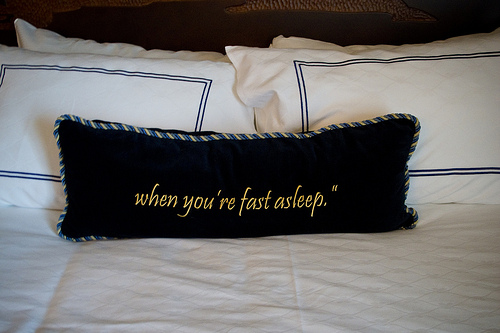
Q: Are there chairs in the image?
A: No, there are no chairs.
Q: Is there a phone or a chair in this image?
A: No, there are no chairs or phones.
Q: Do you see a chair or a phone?
A: No, there are no chairs or phones.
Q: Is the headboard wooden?
A: Yes, the headboard is wooden.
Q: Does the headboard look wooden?
A: Yes, the headboard is wooden.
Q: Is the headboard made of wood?
A: Yes, the headboard is made of wood.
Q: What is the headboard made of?
A: The headboard is made of wood.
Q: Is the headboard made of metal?
A: No, the headboard is made of wood.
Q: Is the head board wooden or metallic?
A: The head board is wooden.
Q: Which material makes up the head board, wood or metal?
A: The head board is made of wood.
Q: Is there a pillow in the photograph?
A: Yes, there are pillows.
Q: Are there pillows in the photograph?
A: Yes, there are pillows.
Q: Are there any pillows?
A: Yes, there are pillows.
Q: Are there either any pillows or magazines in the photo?
A: Yes, there are pillows.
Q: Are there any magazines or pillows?
A: Yes, there are pillows.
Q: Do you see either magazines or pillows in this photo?
A: Yes, there are pillows.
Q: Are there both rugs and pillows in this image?
A: No, there are pillows but no rugs.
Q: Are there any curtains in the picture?
A: No, there are no curtains.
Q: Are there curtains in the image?
A: No, there are no curtains.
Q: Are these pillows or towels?
A: These are pillows.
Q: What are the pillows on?
A: The pillows are on the bed.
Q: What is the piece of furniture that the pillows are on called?
A: The piece of furniture is a bed.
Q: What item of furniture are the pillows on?
A: The pillows are on the bed.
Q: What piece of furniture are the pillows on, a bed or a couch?
A: The pillows are on a bed.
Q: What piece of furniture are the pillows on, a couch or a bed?
A: The pillows are on a bed.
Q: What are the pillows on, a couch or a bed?
A: The pillows are on a bed.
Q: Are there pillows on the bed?
A: Yes, there are pillows on the bed.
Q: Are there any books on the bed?
A: No, there are pillows on the bed.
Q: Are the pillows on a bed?
A: Yes, the pillows are on a bed.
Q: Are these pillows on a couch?
A: No, the pillows are on a bed.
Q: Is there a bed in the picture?
A: Yes, there is a bed.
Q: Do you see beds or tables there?
A: Yes, there is a bed.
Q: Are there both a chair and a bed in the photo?
A: No, there is a bed but no chairs.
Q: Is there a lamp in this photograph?
A: No, there are no lamps.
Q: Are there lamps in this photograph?
A: No, there are no lamps.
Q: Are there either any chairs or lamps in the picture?
A: No, there are no lamps or chairs.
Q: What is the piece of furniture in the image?
A: The piece of furniture is a bed.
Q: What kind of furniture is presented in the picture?
A: The furniture is a bed.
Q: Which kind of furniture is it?
A: The piece of furniture is a bed.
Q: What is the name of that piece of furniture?
A: This is a bed.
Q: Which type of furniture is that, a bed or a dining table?
A: This is a bed.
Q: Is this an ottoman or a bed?
A: This is a bed.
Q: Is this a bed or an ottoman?
A: This is a bed.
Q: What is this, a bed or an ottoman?
A: This is a bed.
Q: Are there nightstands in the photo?
A: No, there are no nightstands.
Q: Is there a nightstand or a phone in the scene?
A: No, there are no nightstands or phones.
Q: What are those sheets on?
A: The sheets are on the bed.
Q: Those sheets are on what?
A: The sheets are on the bed.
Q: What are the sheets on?
A: The sheets are on the bed.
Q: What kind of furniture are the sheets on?
A: The sheets are on the bed.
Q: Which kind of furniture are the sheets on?
A: The sheets are on the bed.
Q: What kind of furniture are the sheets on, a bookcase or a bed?
A: The sheets are on a bed.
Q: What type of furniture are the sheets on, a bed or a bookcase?
A: The sheets are on a bed.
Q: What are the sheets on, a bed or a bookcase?
A: The sheets are on a bed.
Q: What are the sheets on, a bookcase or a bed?
A: The sheets are on a bed.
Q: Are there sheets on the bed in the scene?
A: Yes, there are sheets on the bed.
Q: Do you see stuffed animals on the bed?
A: No, there are sheets on the bed.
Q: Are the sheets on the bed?
A: Yes, the sheets are on the bed.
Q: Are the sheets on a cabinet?
A: No, the sheets are on the bed.